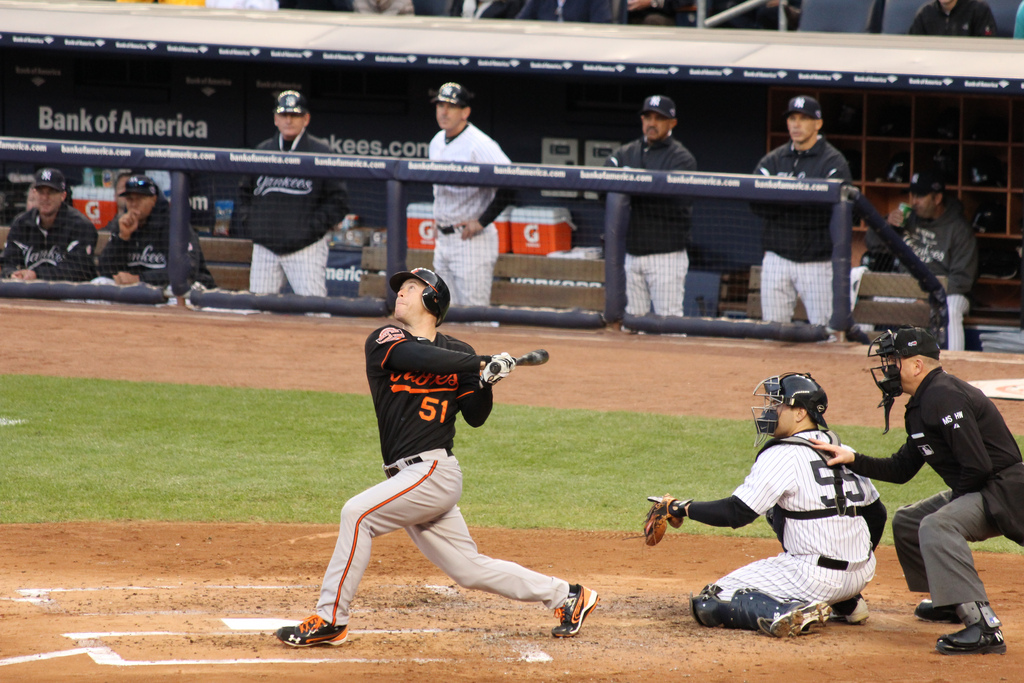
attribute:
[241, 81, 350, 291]
person — standing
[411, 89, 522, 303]
person — standing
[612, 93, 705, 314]
person — standing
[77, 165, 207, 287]
person — sitting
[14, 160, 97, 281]
person — sitting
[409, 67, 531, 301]
person — standing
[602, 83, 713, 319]
person — standing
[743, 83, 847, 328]
person — up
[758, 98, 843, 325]
person — up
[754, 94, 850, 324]
person — up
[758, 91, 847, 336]
person —  up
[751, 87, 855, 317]
person —  up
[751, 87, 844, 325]
person —  up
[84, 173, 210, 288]
person —  down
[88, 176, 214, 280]
person —  down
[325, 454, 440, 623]
stripe — ORANGE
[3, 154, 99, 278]
person — SITTING DOWN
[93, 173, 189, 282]
person — SITTING DOWN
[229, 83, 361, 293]
person — STANDING UP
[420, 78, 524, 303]
person — STANDING UP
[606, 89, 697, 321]
person — STANDING UP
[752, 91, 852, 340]
person — standing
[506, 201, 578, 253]
cooler — white, orange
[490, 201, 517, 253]
cooler — white, orange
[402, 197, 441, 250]
cooler — white, orange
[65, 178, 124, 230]
cooler — white, orange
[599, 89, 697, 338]
person — standing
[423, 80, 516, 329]
person — standing